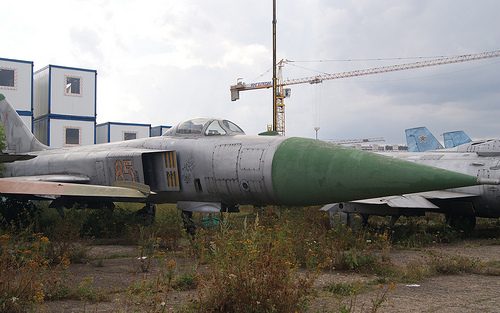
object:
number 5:
[121, 159, 136, 183]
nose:
[266, 133, 499, 209]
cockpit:
[160, 114, 246, 138]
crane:
[230, 0, 500, 135]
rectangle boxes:
[28, 57, 104, 120]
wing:
[0, 165, 158, 210]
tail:
[0, 94, 52, 154]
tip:
[478, 178, 500, 191]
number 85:
[115, 159, 137, 183]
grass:
[0, 198, 499, 313]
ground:
[1, 198, 500, 313]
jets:
[308, 138, 498, 233]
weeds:
[195, 198, 337, 313]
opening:
[139, 149, 181, 193]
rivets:
[234, 161, 240, 166]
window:
[61, 76, 81, 96]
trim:
[49, 64, 98, 72]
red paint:
[1, 178, 134, 202]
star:
[417, 134, 428, 144]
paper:
[403, 280, 426, 294]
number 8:
[111, 159, 124, 184]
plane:
[1, 83, 498, 240]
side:
[0, 141, 382, 208]